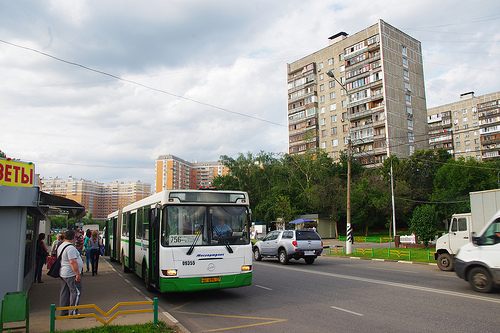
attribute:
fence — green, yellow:
[384, 244, 416, 264]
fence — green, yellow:
[38, 301, 178, 327]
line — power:
[41, 46, 292, 167]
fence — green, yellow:
[45, 295, 166, 331]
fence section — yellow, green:
[327, 244, 347, 256]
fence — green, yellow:
[424, 250, 434, 260]